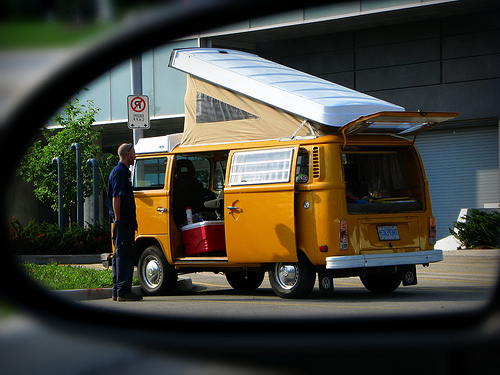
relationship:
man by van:
[105, 142, 142, 303] [107, 46, 446, 290]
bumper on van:
[326, 247, 449, 269] [107, 46, 446, 290]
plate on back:
[375, 223, 401, 240] [328, 132, 437, 254]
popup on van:
[166, 47, 413, 139] [107, 46, 446, 290]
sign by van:
[128, 94, 151, 128] [107, 46, 446, 290]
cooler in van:
[181, 218, 226, 251] [107, 46, 446, 290]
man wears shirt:
[105, 142, 142, 303] [105, 162, 141, 224]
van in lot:
[107, 46, 446, 290] [23, 250, 498, 336]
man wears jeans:
[105, 142, 142, 303] [111, 226, 136, 289]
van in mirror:
[107, 46, 446, 290] [6, 7, 500, 370]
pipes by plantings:
[46, 145, 105, 224] [14, 217, 108, 262]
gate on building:
[413, 123, 497, 241] [18, 4, 496, 257]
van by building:
[107, 46, 446, 290] [18, 4, 496, 257]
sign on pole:
[128, 94, 151, 128] [130, 54, 145, 143]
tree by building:
[22, 98, 118, 227] [18, 4, 496, 257]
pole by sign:
[130, 54, 145, 143] [128, 94, 151, 128]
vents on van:
[307, 142, 325, 182] [107, 46, 446, 290]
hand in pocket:
[111, 210, 122, 221] [112, 216, 119, 226]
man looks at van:
[105, 142, 142, 303] [107, 46, 446, 290]